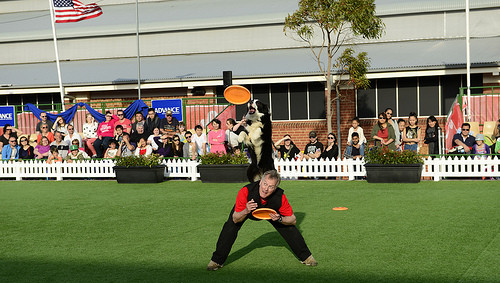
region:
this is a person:
[470, 126, 498, 162]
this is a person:
[408, 110, 448, 162]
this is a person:
[320, 123, 345, 170]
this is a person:
[268, 128, 305, 166]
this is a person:
[203, 109, 234, 163]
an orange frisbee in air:
[223, 83, 254, 106]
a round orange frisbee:
[249, 206, 279, 221]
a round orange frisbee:
[331, 203, 349, 209]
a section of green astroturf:
[2, 179, 498, 281]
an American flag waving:
[54, 0, 103, 25]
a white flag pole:
[48, 0, 65, 105]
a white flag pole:
[463, 0, 471, 120]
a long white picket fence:
[1, 157, 498, 177]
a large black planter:
[110, 155, 167, 182]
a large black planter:
[196, 152, 255, 182]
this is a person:
[204, 153, 339, 278]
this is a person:
[450, 109, 484, 160]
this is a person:
[400, 102, 427, 172]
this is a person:
[340, 112, 374, 163]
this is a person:
[302, 119, 333, 167]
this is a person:
[297, 122, 321, 170]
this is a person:
[197, 106, 235, 164]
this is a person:
[108, 119, 138, 156]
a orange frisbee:
[223, 84, 250, 104]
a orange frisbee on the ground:
[331, 202, 348, 215]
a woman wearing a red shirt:
[377, 125, 390, 150]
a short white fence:
[0, 160, 105, 182]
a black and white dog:
[233, 95, 275, 185]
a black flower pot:
[360, 152, 428, 182]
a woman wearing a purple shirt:
[35, 136, 47, 150]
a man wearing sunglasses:
[460, 123, 471, 138]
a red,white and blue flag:
[48, 2, 110, 27]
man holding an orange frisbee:
[205, 169, 317, 272]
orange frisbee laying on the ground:
[330, 202, 347, 214]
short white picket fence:
[0, 155, 498, 182]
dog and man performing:
[203, 83, 317, 273]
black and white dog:
[234, 95, 279, 184]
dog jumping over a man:
[207, 93, 319, 268]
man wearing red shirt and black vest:
[204, 168, 318, 273]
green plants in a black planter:
[112, 152, 165, 182]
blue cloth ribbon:
[23, 97, 149, 127]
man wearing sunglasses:
[453, 119, 474, 154]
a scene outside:
[4, 3, 499, 279]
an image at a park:
[5, 1, 498, 279]